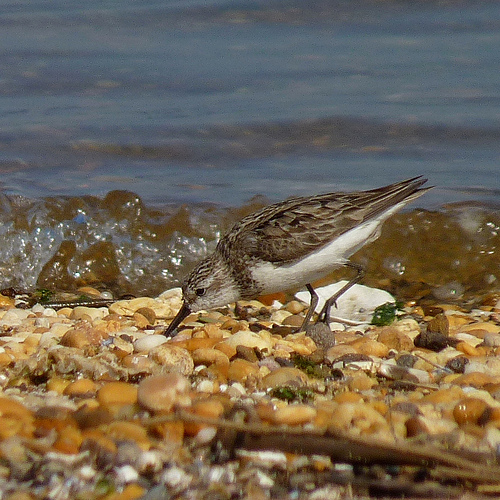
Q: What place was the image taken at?
A: It was taken at the beach.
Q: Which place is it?
A: It is a beach.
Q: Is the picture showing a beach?
A: Yes, it is showing a beach.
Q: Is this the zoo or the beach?
A: It is the beach.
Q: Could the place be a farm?
A: No, it is a beach.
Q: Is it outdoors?
A: Yes, it is outdoors.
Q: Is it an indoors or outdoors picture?
A: It is outdoors.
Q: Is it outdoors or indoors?
A: It is outdoors.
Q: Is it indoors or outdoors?
A: It is outdoors.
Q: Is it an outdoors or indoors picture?
A: It is outdoors.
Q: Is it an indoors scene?
A: No, it is outdoors.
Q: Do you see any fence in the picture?
A: No, there are no fences.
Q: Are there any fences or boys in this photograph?
A: No, there are no fences or boys.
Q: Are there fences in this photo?
A: No, there are no fences.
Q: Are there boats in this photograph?
A: No, there are no boats.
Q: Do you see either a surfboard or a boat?
A: No, there are no boats or surfboards.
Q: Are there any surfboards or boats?
A: No, there are no boats or surfboards.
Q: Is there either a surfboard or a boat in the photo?
A: No, there are no boats or surfboards.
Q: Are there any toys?
A: No, there are no toys.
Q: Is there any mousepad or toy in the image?
A: No, there are no toys or mouse pads.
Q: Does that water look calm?
A: Yes, the water is calm.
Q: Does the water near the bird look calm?
A: Yes, the water is calm.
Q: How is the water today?
A: The water is calm.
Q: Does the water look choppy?
A: No, the water is calm.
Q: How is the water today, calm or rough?
A: The water is calm.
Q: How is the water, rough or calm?
A: The water is calm.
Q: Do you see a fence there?
A: No, there are no fences.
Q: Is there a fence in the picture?
A: No, there are no fences.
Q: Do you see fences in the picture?
A: No, there are no fences.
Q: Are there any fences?
A: No, there are no fences.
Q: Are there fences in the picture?
A: No, there are no fences.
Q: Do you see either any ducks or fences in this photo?
A: No, there are no fences or ducks.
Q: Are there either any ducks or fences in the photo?
A: No, there are no fences or ducks.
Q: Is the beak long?
A: Yes, the beak is long.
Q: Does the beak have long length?
A: Yes, the beak is long.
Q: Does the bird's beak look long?
A: Yes, the beak is long.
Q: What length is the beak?
A: The beak is long.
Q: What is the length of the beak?
A: The beak is long.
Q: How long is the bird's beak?
A: The beak is long.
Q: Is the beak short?
A: No, the beak is long.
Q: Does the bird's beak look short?
A: No, the beak is long.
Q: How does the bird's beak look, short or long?
A: The beak is long.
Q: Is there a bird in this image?
A: Yes, there is a bird.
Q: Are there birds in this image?
A: Yes, there is a bird.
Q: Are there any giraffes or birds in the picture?
A: Yes, there is a bird.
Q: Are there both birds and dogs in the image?
A: No, there is a bird but no dogs.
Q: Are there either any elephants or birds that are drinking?
A: Yes, the bird is drinking.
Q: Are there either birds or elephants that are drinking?
A: Yes, the bird is drinking.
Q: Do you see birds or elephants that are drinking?
A: Yes, the bird is drinking.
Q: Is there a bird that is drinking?
A: Yes, there is a bird that is drinking.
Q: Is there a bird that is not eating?
A: Yes, there is a bird that is drinking.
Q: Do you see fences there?
A: No, there are no fences.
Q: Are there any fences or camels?
A: No, there are no fences or camels.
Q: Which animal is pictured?
A: The animal is a bird.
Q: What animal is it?
A: The animal is a bird.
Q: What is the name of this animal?
A: This is a bird.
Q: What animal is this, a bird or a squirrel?
A: This is a bird.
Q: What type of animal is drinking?
A: The animal is a bird.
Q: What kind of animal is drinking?
A: The animal is a bird.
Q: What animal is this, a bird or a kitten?
A: This is a bird.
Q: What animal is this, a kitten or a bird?
A: This is a bird.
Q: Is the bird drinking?
A: Yes, the bird is drinking.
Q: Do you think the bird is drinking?
A: Yes, the bird is drinking.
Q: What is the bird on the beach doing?
A: The bird is drinking.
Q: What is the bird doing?
A: The bird is drinking.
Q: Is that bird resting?
A: No, the bird is drinking.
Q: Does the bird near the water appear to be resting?
A: No, the bird is drinking.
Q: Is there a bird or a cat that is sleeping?
A: No, there is a bird but it is drinking.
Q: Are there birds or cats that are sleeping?
A: No, there is a bird but it is drinking.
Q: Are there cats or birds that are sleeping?
A: No, there is a bird but it is drinking.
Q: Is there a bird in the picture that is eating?
A: No, there is a bird but it is drinking.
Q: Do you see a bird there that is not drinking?
A: No, there is a bird but it is drinking.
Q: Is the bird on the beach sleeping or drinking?
A: The bird is drinking.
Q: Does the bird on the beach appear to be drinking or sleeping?
A: The bird is drinking.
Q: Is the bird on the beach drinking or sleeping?
A: The bird is drinking.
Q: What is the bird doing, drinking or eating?
A: The bird is drinking.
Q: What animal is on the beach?
A: The bird is on the beach.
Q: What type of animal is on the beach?
A: The animal is a bird.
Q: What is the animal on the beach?
A: The animal is a bird.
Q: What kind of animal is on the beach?
A: The animal is a bird.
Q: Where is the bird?
A: The bird is on the beach.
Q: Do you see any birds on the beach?
A: Yes, there is a bird on the beach.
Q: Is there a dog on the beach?
A: No, there is a bird on the beach.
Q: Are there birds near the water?
A: Yes, there is a bird near the water.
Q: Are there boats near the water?
A: No, there is a bird near the water.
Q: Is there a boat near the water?
A: No, there is a bird near the water.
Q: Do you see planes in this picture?
A: No, there are no planes.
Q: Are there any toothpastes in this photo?
A: No, there are no toothpastes.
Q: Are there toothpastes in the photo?
A: No, there are no toothpastes.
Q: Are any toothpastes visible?
A: No, there are no toothpastes.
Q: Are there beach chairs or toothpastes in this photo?
A: No, there are no toothpastes or beach chairs.